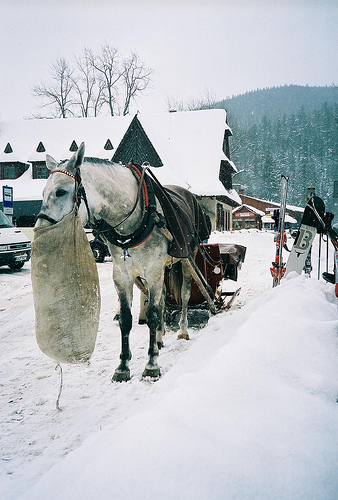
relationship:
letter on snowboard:
[296, 228, 311, 253] [281, 194, 326, 282]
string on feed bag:
[52, 362, 65, 410] [29, 203, 100, 365]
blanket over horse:
[150, 180, 210, 260] [30, 148, 207, 385]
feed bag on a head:
[29, 203, 100, 365] [32, 141, 107, 229]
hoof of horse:
[142, 358, 163, 387] [30, 148, 207, 385]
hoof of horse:
[108, 361, 133, 383] [30, 148, 207, 385]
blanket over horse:
[154, 184, 212, 258] [30, 148, 207, 385]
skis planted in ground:
[268, 175, 287, 292] [243, 305, 334, 457]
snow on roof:
[1, 102, 241, 207] [1, 108, 243, 204]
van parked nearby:
[4, 213, 16, 300] [0, 336, 35, 400]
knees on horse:
[109, 300, 166, 337] [30, 148, 207, 385]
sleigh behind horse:
[181, 258, 237, 314] [42, 157, 185, 378]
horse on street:
[30, 148, 207, 385] [1, 218, 336, 499]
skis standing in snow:
[313, 201, 335, 295] [159, 233, 337, 434]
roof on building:
[1, 113, 165, 203] [133, 106, 243, 228]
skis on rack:
[282, 195, 326, 278] [320, 207, 337, 287]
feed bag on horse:
[29, 203, 100, 365] [30, 148, 207, 385]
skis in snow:
[282, 195, 326, 278] [246, 271, 337, 366]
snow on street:
[18, 276, 336, 499] [4, 308, 196, 440]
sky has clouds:
[65, 5, 254, 73] [0, 0, 337, 119]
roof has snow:
[1, 108, 243, 204] [1, 107, 336, 498]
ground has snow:
[39, 393, 327, 479] [224, 294, 297, 455]